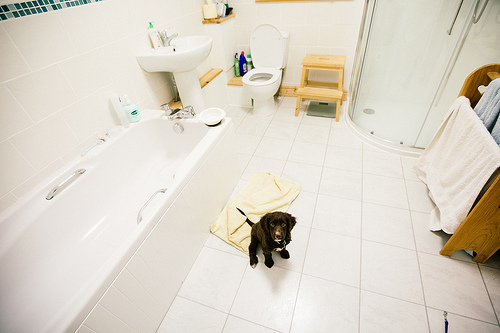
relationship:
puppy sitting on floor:
[237, 207, 297, 269] [157, 97, 499, 331]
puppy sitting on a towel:
[237, 207, 297, 269] [209, 168, 301, 255]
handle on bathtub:
[43, 167, 85, 200] [3, 103, 236, 331]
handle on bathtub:
[133, 185, 164, 226] [3, 103, 236, 331]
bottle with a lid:
[145, 18, 162, 49] [146, 17, 157, 29]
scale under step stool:
[303, 99, 340, 120] [293, 53, 349, 122]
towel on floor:
[209, 168, 301, 255] [157, 97, 499, 331]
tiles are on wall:
[1, 0, 102, 24] [0, 1, 363, 217]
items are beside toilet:
[232, 47, 254, 76] [240, 22, 289, 115]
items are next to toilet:
[232, 47, 254, 76] [240, 22, 289, 115]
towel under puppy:
[209, 168, 301, 255] [237, 207, 297, 269]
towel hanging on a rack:
[412, 92, 497, 235] [435, 60, 498, 261]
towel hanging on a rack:
[472, 77, 498, 142] [435, 60, 498, 261]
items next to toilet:
[232, 47, 254, 76] [240, 22, 289, 115]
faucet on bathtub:
[164, 106, 195, 121] [3, 103, 236, 331]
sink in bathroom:
[137, 31, 215, 108] [3, 2, 498, 332]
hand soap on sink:
[145, 18, 162, 49] [137, 31, 215, 108]